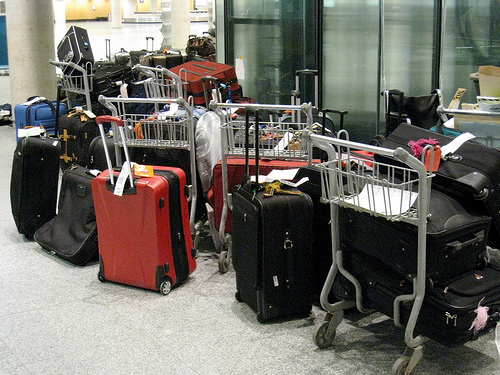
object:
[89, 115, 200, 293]
case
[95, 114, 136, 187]
handle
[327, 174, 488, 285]
bag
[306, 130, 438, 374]
cart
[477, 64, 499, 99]
box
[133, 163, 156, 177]
tag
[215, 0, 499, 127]
wall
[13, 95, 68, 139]
suitcase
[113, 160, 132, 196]
badge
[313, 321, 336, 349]
wheel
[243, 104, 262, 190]
holder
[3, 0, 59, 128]
pillar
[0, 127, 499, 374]
floor